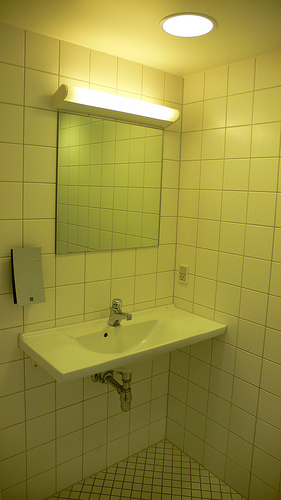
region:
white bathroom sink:
[11, 302, 228, 380]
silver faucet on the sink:
[107, 298, 130, 326]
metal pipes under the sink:
[99, 369, 135, 413]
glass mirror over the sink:
[55, 114, 162, 251]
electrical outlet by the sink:
[178, 265, 186, 281]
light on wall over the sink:
[52, 88, 178, 126]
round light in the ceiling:
[161, 11, 212, 38]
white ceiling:
[1, 0, 279, 77]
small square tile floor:
[34, 439, 249, 499]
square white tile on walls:
[2, 23, 278, 499]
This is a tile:
[82, 422, 110, 456]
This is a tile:
[54, 405, 92, 436]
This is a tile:
[129, 402, 155, 430]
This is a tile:
[164, 394, 188, 432]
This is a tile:
[188, 387, 210, 419]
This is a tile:
[204, 388, 233, 434]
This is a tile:
[204, 365, 238, 401]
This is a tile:
[214, 277, 248, 319]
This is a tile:
[215, 250, 249, 286]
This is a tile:
[196, 246, 224, 285]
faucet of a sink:
[101, 292, 136, 327]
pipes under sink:
[94, 368, 140, 413]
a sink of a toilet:
[65, 313, 188, 359]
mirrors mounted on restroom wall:
[48, 82, 185, 258]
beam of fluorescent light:
[48, 87, 182, 130]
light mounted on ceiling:
[155, 4, 218, 44]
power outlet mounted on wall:
[177, 260, 189, 284]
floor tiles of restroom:
[88, 443, 222, 497]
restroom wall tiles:
[171, 362, 277, 443]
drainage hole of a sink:
[102, 329, 109, 337]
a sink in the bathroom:
[67, 336, 118, 350]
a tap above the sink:
[103, 304, 132, 319]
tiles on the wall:
[185, 136, 253, 270]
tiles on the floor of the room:
[152, 449, 183, 490]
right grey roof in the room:
[79, 8, 146, 38]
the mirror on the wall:
[64, 142, 149, 236]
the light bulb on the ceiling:
[168, 13, 204, 33]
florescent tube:
[70, 80, 173, 115]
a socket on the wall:
[178, 269, 187, 279]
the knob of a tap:
[114, 301, 123, 310]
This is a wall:
[5, 28, 176, 481]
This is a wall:
[178, 60, 267, 496]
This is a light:
[39, 81, 195, 160]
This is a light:
[155, 7, 224, 51]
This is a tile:
[23, 413, 56, 443]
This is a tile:
[161, 371, 190, 409]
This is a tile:
[207, 338, 235, 373]